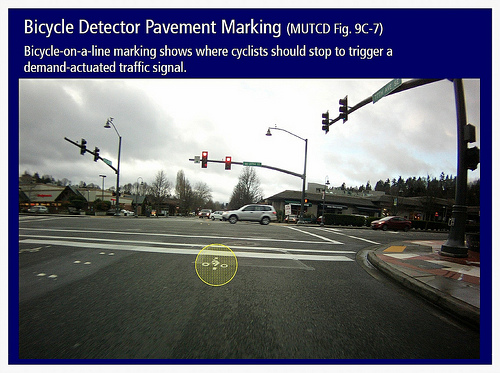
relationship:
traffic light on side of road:
[318, 105, 332, 137] [19, 214, 455, 365]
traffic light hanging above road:
[335, 94, 349, 124] [19, 213, 450, 243]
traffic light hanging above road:
[92, 146, 101, 162] [19, 212, 447, 249]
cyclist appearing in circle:
[197, 255, 229, 272] [193, 240, 240, 289]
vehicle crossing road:
[220, 201, 279, 225] [19, 212, 447, 249]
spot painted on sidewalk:
[382, 243, 408, 254] [373, 234, 481, 309]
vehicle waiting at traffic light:
[368, 213, 419, 232] [92, 146, 100, 161]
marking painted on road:
[19, 236, 354, 263] [19, 214, 455, 365]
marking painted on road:
[19, 236, 354, 263] [19, 212, 447, 249]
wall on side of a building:
[286, 192, 449, 228] [260, 177, 475, 233]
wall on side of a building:
[23, 188, 83, 207] [19, 182, 180, 215]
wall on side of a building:
[120, 201, 171, 213] [19, 182, 180, 215]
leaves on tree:
[377, 179, 395, 195] [372, 178, 395, 194]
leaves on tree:
[395, 176, 417, 191] [396, 173, 418, 187]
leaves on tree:
[29, 171, 51, 188] [29, 168, 52, 188]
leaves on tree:
[425, 176, 451, 195] [427, 174, 451, 191]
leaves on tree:
[405, 177, 424, 193] [401, 173, 428, 192]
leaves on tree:
[371, 176, 390, 192] [377, 173, 399, 192]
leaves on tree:
[29, 169, 50, 185] [31, 170, 63, 184]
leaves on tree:
[184, 184, 193, 211] [174, 164, 202, 217]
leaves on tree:
[31, 171, 55, 185] [33, 168, 51, 185]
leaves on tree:
[427, 172, 448, 194] [434, 171, 456, 193]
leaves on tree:
[405, 172, 425, 193] [410, 174, 434, 192]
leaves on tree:
[383, 174, 409, 194] [373, 176, 394, 195]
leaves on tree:
[229, 184, 252, 204] [226, 180, 256, 208]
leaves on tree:
[178, 179, 192, 211] [176, 173, 197, 211]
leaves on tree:
[433, 174, 455, 194] [425, 171, 453, 197]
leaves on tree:
[391, 176, 419, 196] [392, 175, 428, 191]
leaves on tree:
[338, 180, 357, 192] [336, 179, 353, 193]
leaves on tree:
[402, 170, 425, 192] [393, 176, 414, 194]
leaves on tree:
[437, 169, 457, 195] [402, 175, 422, 195]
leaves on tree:
[32, 169, 55, 187] [31, 166, 47, 186]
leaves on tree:
[360, 177, 388, 191] [357, 177, 373, 191]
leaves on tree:
[387, 176, 409, 192] [376, 173, 406, 193]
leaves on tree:
[406, 171, 426, 194] [407, 173, 442, 192]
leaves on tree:
[429, 173, 453, 194] [436, 176, 456, 201]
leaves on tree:
[31, 171, 55, 185] [31, 169, 54, 190]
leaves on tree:
[182, 173, 202, 203] [172, 194, 195, 213]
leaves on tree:
[176, 181, 191, 211] [169, 204, 181, 216]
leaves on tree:
[395, 176, 417, 191] [413, 199, 423, 218]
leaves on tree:
[413, 168, 433, 190] [414, 201, 436, 215]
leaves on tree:
[401, 169, 417, 183] [412, 202, 424, 209]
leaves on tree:
[438, 174, 450, 203] [426, 206, 444, 223]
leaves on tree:
[230, 156, 264, 203] [227, 197, 244, 206]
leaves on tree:
[182, 177, 203, 203] [181, 206, 196, 214]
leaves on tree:
[156, 168, 171, 183] [158, 197, 168, 211]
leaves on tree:
[154, 167, 166, 189] [149, 196, 159, 206]